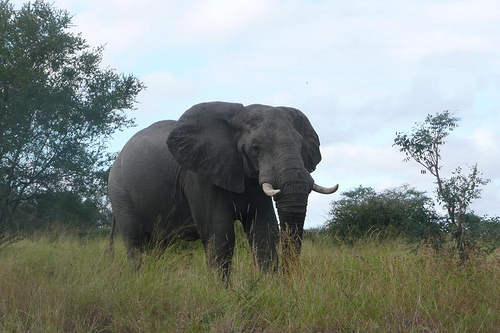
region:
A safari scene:
[2, 3, 496, 329]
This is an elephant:
[104, 98, 341, 283]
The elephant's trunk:
[271, 147, 312, 282]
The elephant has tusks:
[257, 180, 342, 198]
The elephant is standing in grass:
[0, 98, 498, 329]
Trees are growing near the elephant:
[1, 0, 498, 244]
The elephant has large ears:
[165, 100, 322, 191]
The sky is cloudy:
[143, 3, 493, 182]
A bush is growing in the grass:
[329, 182, 438, 245]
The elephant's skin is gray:
[104, 100, 341, 285]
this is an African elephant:
[90, 89, 352, 292]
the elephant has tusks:
[256, 170, 348, 217]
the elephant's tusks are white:
[250, 170, 352, 217]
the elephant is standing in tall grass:
[93, 95, 348, 311]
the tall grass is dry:
[1, 220, 498, 332]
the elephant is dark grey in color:
[99, 99, 344, 296]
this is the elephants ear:
[156, 77, 251, 208]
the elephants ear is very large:
[156, 88, 252, 225]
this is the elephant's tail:
[99, 207, 123, 260]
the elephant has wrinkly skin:
[78, 88, 353, 307]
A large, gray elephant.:
[103, 98, 339, 287]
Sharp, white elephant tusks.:
[257, 178, 341, 197]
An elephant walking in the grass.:
[97, 99, 342, 276]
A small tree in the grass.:
[393, 108, 493, 261]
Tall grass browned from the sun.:
[0, 227, 499, 331]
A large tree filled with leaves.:
[0, 0, 145, 248]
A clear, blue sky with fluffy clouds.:
[2, 0, 499, 230]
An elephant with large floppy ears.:
[104, 100, 339, 282]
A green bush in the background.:
[321, 183, 446, 245]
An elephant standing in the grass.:
[103, 98, 340, 275]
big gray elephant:
[108, 96, 321, 284]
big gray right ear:
[165, 100, 251, 192]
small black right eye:
[250, 141, 262, 153]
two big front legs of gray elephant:
[190, 185, 281, 292]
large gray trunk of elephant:
[265, 157, 307, 282]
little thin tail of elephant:
[104, 197, 117, 264]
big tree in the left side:
[0, 0, 146, 244]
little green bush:
[331, 184, 433, 244]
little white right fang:
[259, 178, 279, 198]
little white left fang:
[309, 180, 339, 194]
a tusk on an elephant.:
[307, 165, 351, 202]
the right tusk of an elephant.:
[252, 180, 294, 205]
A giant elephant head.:
[159, 90, 346, 285]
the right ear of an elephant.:
[160, 103, 269, 211]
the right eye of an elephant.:
[246, 138, 271, 160]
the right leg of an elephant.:
[179, 195, 247, 292]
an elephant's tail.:
[96, 205, 123, 274]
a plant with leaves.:
[371, 96, 486, 271]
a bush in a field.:
[326, 186, 461, 250]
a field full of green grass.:
[9, 238, 499, 329]